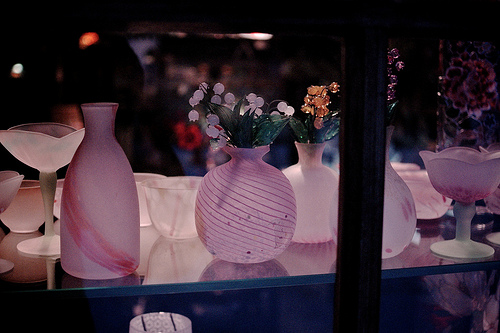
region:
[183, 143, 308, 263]
wavy pattern on vase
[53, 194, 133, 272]
red color on the vase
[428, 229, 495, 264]
broad base on vase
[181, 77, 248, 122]
white flowers in the vase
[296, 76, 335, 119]
brilliant gold flower stalks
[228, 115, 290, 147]
green leaves on flowers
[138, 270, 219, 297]
blue edge on table top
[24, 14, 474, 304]
these are vases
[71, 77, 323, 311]
the vases are pink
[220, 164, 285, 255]
the vases are purple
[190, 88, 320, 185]
these are flower vases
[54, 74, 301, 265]
the vases are pastel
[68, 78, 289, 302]
the vases are translucent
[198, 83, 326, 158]
the vases are glass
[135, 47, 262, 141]
the background is lit up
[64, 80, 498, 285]
this shelf is dark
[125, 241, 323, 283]
the shelf is glass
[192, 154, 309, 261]
a round vase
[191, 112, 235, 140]
a white flower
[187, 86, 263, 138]
flowers in the vase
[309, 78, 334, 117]
orange flowers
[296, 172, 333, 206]
a vase on the counter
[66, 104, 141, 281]
a vase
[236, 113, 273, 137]
green leaves in the vase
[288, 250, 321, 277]
a counter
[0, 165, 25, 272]
The glass that is cut off to the left.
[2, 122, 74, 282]
The wine glass that looks like a flower.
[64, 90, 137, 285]
The tallest pink and white vase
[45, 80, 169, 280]
The vase with no flowers in it.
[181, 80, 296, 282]
The vase with little white flowers in it.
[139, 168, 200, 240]
The cup behind the vase with white flowers in it.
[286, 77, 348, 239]
The vase with little orange flowers in it.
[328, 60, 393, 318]
The brown pole in front the vases.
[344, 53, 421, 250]
The vase partially hidden by the vase.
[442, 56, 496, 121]
The big flower behind the glass.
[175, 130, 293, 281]
white and round vase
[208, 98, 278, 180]
green stems on plants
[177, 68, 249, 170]
white flowers on plants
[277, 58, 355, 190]
yellow flowers on plants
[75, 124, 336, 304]
vases on reflective surface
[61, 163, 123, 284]
red stripe on vase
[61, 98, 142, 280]
Tall pink vase on a table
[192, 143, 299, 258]
Pink striped vase on a table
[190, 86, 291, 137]
White flowers in a vase